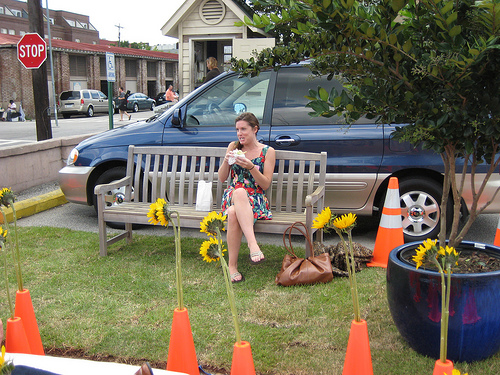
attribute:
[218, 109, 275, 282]
woman — sitting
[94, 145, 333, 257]
bench — grey, wooden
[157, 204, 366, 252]
sunflowers — yellow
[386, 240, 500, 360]
flower pot — blue, big, large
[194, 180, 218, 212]
bag — white, brown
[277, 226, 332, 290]
bag — light brown, leather, brown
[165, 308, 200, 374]
traffic cone — orange, white, big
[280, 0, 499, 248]
tree — small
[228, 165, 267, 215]
sundress — colorful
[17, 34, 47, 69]
stop sign — red, white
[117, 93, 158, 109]
car — parked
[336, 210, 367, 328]
sunflower — petaled, large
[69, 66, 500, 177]
van — blue, silver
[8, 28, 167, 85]
building — brick